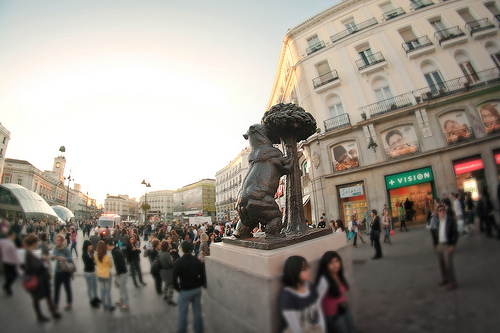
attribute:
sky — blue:
[3, 0, 282, 160]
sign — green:
[383, 162, 433, 192]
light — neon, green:
[373, 157, 433, 195]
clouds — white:
[57, 17, 229, 157]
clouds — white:
[41, 36, 92, 60]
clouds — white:
[198, 47, 256, 75]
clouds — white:
[142, 40, 178, 61]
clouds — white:
[104, 43, 129, 66]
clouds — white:
[3, 65, 23, 87]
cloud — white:
[4, 40, 262, 206]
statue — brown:
[226, 97, 321, 238]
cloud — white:
[79, 27, 201, 73]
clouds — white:
[6, 6, 268, 192]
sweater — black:
[172, 254, 200, 281]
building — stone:
[259, 0, 497, 225]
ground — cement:
[377, 269, 449, 331]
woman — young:
[278, 254, 329, 326]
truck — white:
[93, 212, 120, 239]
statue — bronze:
[213, 94, 335, 252]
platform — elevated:
[192, 226, 364, 331]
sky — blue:
[0, 3, 350, 216]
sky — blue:
[1, 3, 342, 193]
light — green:
[389, 165, 440, 191]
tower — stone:
[42, 142, 71, 192]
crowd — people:
[7, 206, 200, 302]